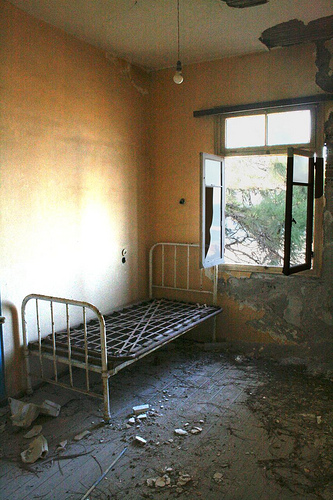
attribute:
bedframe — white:
[20, 239, 219, 421]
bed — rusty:
[19, 238, 222, 428]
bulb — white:
[168, 58, 192, 88]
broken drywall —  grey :
[222, 273, 332, 345]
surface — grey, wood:
[2, 338, 332, 499]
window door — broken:
[280, 148, 312, 273]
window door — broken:
[198, 152, 225, 267]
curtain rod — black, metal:
[193, 90, 331, 118]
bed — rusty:
[23, 262, 226, 401]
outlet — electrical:
[121, 247, 128, 263]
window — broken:
[197, 154, 324, 272]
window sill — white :
[213, 264, 318, 276]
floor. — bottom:
[163, 383, 281, 456]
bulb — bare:
[162, 55, 209, 99]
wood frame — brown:
[198, 151, 224, 269]